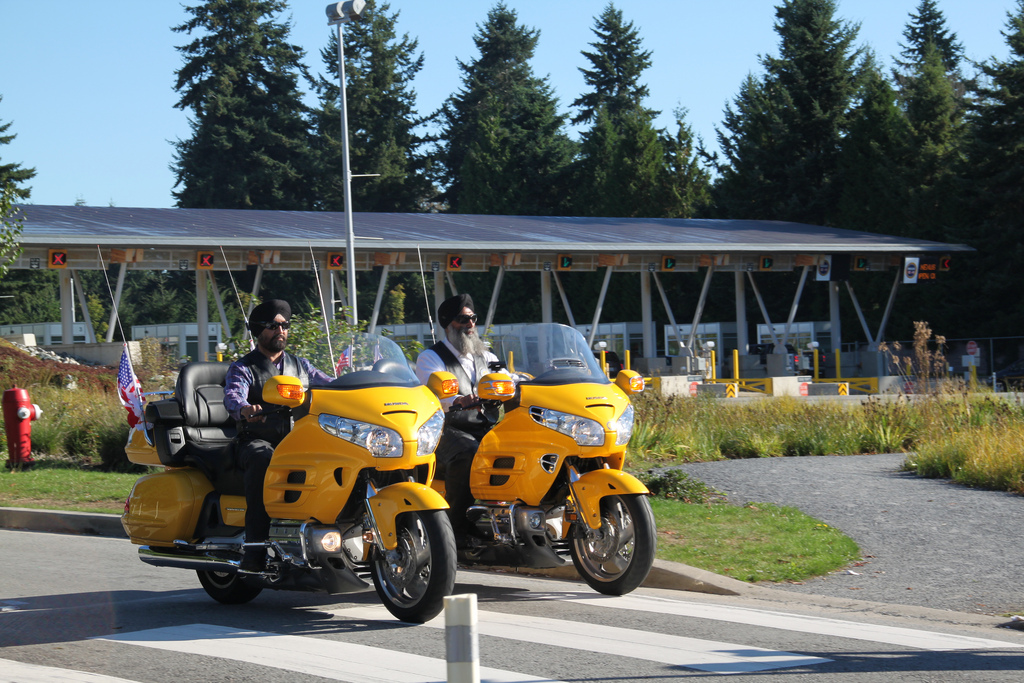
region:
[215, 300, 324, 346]
Man wearing black sunglasses on face.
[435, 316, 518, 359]
Man has long gray beard on face.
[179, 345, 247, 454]
Back seat on bike is black leather.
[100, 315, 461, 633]
Man riding on yellow bike.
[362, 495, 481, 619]
Front tire on bike is black.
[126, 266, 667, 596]
2 men riding on yellow motorcycles.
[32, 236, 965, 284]
Red and green lights illuminated on building.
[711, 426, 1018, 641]
Stone path in between long grass.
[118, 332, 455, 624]
A yellow motorcycle on the road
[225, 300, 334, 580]
A man with dark hair on a motorcycle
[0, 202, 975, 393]
A toll booth on a highway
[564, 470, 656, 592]
The front wheel of a yellow motorcycle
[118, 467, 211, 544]
The luggage compartment of a motorcycle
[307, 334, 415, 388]
The windshield of a motorcycle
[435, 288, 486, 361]
The face of a man with a beard and hat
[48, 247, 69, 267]
A sign at a toll booth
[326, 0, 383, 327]
A sign pole on the road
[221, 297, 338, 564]
man wearing purple shirt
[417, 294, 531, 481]
man wearing white shirt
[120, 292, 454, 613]
yellow motorcycle ridden by man in purple shirt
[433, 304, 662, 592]
yellow motorcycle ridden by man in white shirt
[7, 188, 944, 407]
shelter behind the yellow motorcycles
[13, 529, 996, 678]
shadows on the street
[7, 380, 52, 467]
red and white fire hydrant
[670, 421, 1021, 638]
paved path next to the road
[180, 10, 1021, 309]
trees behind the shelter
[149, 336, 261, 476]
black seat on the yellow motorcycle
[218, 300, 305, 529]
A man on a motorcycle.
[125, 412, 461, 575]
The motorcycle is yellow.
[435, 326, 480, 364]
The man has a grey beard.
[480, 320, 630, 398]
The shield on the motorcycle.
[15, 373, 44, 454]
A red fire hydrant on grass.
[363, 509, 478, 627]
Front wheel of the motorcycle.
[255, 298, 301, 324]
the man is wearing sunglasses.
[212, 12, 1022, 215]
The green trees are tall.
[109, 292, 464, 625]
A yellow motorcycle.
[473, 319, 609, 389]
A glass wind shield.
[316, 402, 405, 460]
A front right headlight.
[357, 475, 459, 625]
A front tire on a bike.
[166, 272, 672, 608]
two motorcycles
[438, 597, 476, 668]
a pole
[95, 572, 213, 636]
a shadow on the ground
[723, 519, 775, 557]
the grass is low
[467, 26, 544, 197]
a tall tree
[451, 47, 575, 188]
a tall green tree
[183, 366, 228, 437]
the seat is black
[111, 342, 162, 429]
a flag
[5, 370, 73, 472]
red fire hydrant beside road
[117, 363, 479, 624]
yellow motorcycle on road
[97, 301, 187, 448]
flag on back of motorcycle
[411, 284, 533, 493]
man with long beard on motorcycle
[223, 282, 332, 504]
man wearing turban on head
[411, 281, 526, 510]
man wearing white shirt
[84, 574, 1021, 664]
white lines on road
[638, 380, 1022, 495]
weeds by the road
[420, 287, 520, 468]
man wearing white shirt and turban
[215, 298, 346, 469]
man in purple shirt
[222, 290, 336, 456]
man in purple shirt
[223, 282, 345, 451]
man in purple shirt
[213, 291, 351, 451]
man in purple shirt